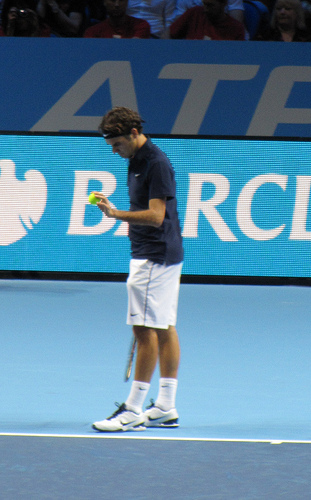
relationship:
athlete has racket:
[50, 81, 243, 330] [124, 331, 139, 380]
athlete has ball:
[50, 81, 243, 330] [87, 191, 101, 204]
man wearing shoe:
[67, 107, 205, 440] [91, 400, 145, 431]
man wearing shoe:
[67, 107, 205, 440] [144, 397, 179, 427]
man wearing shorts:
[67, 107, 205, 440] [120, 253, 180, 328]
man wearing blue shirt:
[67, 107, 205, 440] [117, 129, 184, 264]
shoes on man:
[86, 403, 186, 430] [67, 107, 205, 440]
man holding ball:
[67, 107, 205, 440] [87, 191, 101, 204]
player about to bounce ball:
[88, 108, 181, 435] [88, 192, 101, 206]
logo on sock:
[136, 382, 148, 392] [124, 379, 150, 411]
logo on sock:
[158, 382, 168, 389] [154, 377, 177, 410]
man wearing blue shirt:
[67, 107, 205, 440] [126, 151, 182, 260]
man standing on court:
[67, 107, 205, 440] [20, 295, 304, 377]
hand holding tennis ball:
[91, 190, 113, 217] [87, 188, 103, 205]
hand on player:
[91, 190, 113, 217] [92, 103, 183, 298]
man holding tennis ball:
[67, 107, 205, 440] [87, 192, 100, 204]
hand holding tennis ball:
[91, 190, 113, 217] [87, 192, 100, 204]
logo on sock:
[136, 382, 148, 392] [122, 380, 150, 414]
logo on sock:
[158, 382, 168, 389] [151, 376, 177, 411]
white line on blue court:
[4, 427, 309, 447] [25, 303, 298, 430]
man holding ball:
[67, 107, 205, 440] [59, 167, 122, 236]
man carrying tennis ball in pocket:
[67, 107, 205, 440] [138, 254, 167, 272]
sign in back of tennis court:
[51, 130, 276, 278] [6, 280, 310, 498]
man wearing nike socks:
[67, 107, 205, 440] [124, 372, 177, 411]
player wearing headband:
[88, 108, 181, 435] [102, 127, 140, 136]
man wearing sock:
[67, 107, 205, 440] [124, 379, 150, 411]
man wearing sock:
[67, 107, 205, 440] [154, 377, 177, 410]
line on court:
[0, 431, 309, 445] [1, 426, 309, 498]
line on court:
[0, 431, 309, 445] [2, 279, 310, 498]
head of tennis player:
[92, 105, 146, 164] [90, 104, 186, 431]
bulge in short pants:
[122, 272, 141, 294] [122, 252, 181, 329]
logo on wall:
[0, 156, 310, 251] [0, 133, 310, 280]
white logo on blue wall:
[27, 58, 310, 137] [0, 37, 310, 135]